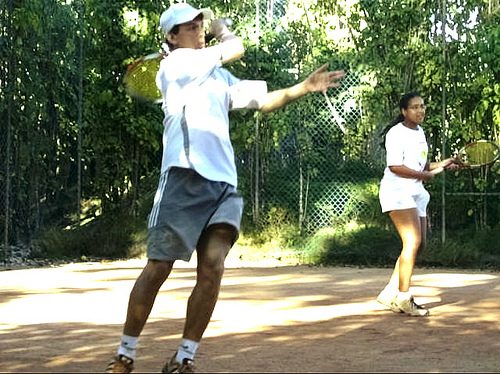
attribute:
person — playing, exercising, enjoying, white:
[105, 3, 348, 373]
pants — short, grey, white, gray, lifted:
[147, 166, 244, 262]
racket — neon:
[420, 138, 499, 180]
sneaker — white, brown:
[391, 295, 430, 316]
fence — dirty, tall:
[1, 1, 498, 254]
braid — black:
[379, 115, 405, 136]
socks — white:
[174, 338, 198, 365]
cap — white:
[158, 3, 212, 38]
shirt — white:
[156, 47, 268, 185]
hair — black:
[380, 92, 423, 133]